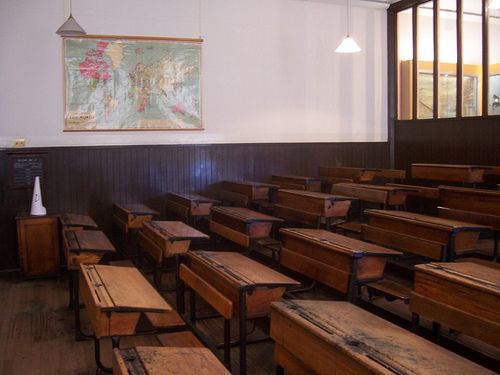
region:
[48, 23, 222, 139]
map on wall of classroom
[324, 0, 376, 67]
light hanging from ceiling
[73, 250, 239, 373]
wooden desk and seat in classroom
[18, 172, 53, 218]
white cone on top of wooden table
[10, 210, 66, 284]
wood table in classroom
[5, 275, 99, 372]
hardwood floors in classroom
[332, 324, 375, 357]
lack blemish on surface of wooden desk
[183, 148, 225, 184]
white light reflected on wood panel wall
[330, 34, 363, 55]
white trinagular lampshade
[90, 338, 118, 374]
metal legs of desk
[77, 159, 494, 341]
brown desks in room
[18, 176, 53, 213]
white dunce cap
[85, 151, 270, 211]
brown wall behind desks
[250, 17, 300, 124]
white wall near ceiling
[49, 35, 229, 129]
large world map on wall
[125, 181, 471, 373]
wooden desks in room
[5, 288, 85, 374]
brown and wooden floor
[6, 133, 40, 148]
white light switch on wall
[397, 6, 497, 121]
wooden slats on wall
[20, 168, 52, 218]
white cone on wooden table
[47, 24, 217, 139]
map on wall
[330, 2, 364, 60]
light hanging from ceiling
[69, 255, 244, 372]
wooden desk and chair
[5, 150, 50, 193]
black board on wall with white writing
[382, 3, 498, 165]
wooden spokes on wall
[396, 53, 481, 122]
wood and glass case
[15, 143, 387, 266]
dark wood paneled lower wall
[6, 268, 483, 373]
hardwood floors in classroom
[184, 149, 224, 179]
white light reflected on wood panelled wall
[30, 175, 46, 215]
the white dunce cap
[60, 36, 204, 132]
the map hanging on the wall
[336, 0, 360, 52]
the light hanging from the ceiling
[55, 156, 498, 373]
the room filled with desks and chairs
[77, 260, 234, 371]
the desk attached to the chair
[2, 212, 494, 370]
the floor made of wood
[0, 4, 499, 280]
the dark wood on the walls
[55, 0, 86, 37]
the light hanging from the ceiling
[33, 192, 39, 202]
the letter "D" on the Dunce cap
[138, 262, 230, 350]
the seating for the desk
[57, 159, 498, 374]
a group of old style school desks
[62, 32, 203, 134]
a map of the world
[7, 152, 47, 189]
a small sign on the wall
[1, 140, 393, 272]
wooden wall paneling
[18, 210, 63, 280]
a small wooden stand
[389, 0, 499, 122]
a grouping of windows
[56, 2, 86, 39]
a hanging light fixture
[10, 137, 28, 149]
a light switch on wall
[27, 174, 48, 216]
a white dunce cap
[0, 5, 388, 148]
white painted wall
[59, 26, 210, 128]
colorful map on wall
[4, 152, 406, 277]
dark brown baseboard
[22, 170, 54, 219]
white dunce cap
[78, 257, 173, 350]
empty wooden desk top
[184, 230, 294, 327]
empty wooden desk top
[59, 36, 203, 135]
map of the countries on the wall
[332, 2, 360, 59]
white light hanging from the ceiling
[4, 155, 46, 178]
chalkboard on the wall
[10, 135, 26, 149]
outlet on the white wall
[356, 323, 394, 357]
black scuff marks on the desk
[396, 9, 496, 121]
windows with bars on the wall